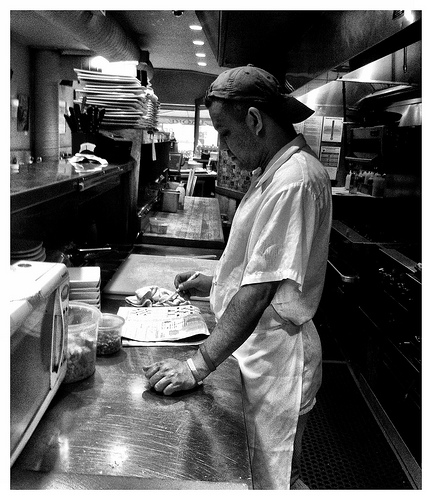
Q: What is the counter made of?
A: Aluminum.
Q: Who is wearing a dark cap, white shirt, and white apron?
A: The food service worker.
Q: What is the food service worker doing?
A: Writing on the newspaper.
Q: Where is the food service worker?
A: In the kitchen.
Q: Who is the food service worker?
A: A man.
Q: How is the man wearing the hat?
A: Backwards.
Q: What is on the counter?
A: Newspaper.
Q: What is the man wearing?
A: An apron.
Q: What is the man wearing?
A: White shirt.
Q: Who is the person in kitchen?
A: A chef.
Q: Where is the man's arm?
A: On the table.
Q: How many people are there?
A: One.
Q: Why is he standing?
A: To read the paper.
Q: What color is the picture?
A: Black and white.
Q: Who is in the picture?
A: A man.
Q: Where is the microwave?
A: On the counter.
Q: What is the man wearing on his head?
A: A cap.